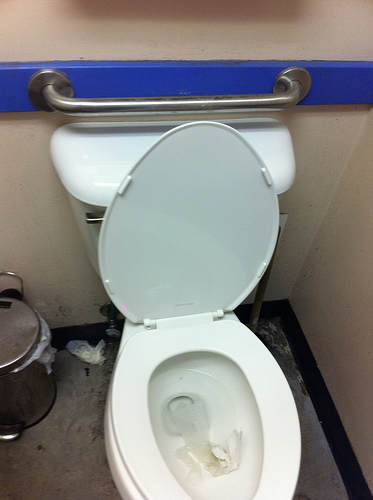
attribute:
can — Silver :
[1, 286, 58, 443]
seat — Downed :
[119, 310, 305, 497]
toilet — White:
[85, 162, 341, 483]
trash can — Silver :
[1, 262, 70, 449]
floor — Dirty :
[1, 317, 354, 497]